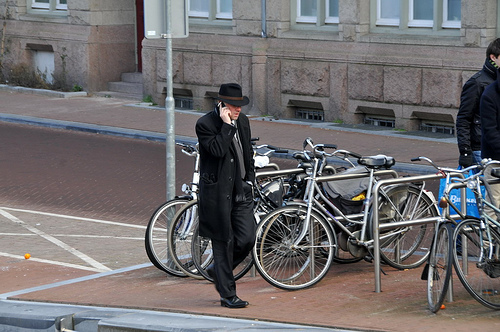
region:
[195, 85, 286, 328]
the man is talking on the phone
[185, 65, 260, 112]
the man has a black hat on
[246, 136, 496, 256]
the bicycles are parked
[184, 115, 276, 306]
the man is all dressed in black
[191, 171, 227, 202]
the man has gloves in his pocket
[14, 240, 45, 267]
there is an orange on the floor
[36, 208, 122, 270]
the road has white stripes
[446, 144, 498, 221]
the man is carrying a blue bag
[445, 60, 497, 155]
there are two people walking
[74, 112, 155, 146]
the curb is blue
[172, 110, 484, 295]
the bikes are parked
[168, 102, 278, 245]
man is wearing coat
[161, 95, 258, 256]
the coat is black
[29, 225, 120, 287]
the line is white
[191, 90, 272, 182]
man is talking on the phone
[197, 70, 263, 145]
the man is wearing a hat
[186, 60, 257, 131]
the hat is black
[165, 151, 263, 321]
the man is wearing pants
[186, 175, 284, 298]
the pants are black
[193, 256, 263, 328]
the shoe is black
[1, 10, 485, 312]
Picture is taken outside.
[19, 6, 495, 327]
Picture is taken during the daytime.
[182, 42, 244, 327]
A man is walking on the sidewalk.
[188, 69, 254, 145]
A man is wearing a black hat.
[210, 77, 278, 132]
A man is holding a cell phone to his ear.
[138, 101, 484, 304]
Many bikes are parked on the sidewalk.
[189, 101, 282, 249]
The man is wearing a black coat.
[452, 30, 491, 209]
A man is holding a blue bag.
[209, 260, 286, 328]
The man's shoe is black.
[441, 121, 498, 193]
A man is wearing black gloves.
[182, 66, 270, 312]
man talking on phone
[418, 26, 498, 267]
man holding shopping bag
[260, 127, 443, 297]
bicycles in stand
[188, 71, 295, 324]
man wearing a hat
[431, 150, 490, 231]
blue bag in mans hand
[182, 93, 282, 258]
man wearing long coat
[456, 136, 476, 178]
man wearing gloves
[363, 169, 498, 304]
pole to tie up bicycles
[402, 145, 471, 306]
bicycle with turned wheel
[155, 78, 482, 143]
basement windows on building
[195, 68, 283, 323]
man is wearing a coat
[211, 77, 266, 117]
man is wearing a hat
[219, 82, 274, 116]
the hat is black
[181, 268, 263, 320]
the shoes are black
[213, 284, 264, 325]
man is wearing shoes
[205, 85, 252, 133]
man is holding a phone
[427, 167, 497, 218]
the bag is blue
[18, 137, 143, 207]
the floor is brown